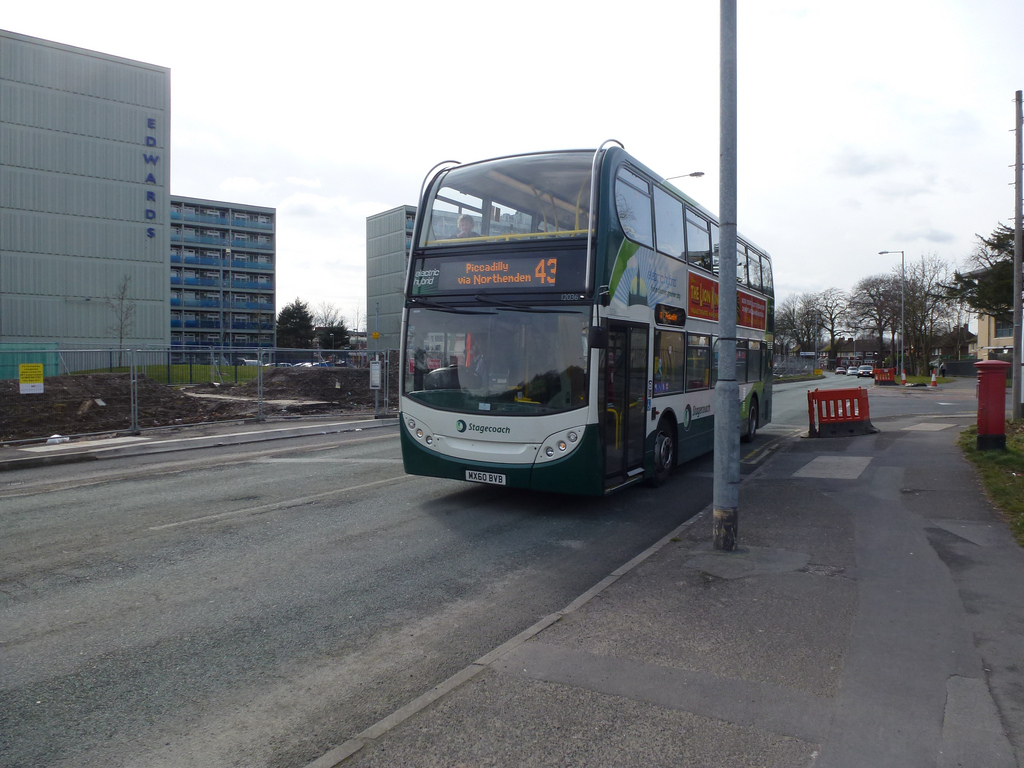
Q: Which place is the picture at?
A: It is at the sidewalk.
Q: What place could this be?
A: It is a sidewalk.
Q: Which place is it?
A: It is a sidewalk.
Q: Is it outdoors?
A: Yes, it is outdoors.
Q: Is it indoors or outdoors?
A: It is outdoors.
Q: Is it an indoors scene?
A: No, it is outdoors.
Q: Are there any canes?
A: No, there are no canes.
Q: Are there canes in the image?
A: No, there are no canes.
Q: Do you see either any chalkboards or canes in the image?
A: No, there are no canes or chalkboards.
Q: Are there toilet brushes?
A: No, there are no toilet brushes.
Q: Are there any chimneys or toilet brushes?
A: No, there are no toilet brushes or chimneys.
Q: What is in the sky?
A: The clouds are in the sky.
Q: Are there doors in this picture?
A: Yes, there is a door.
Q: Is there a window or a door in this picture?
A: Yes, there is a door.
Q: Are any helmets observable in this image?
A: No, there are no helmets.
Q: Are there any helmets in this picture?
A: No, there are no helmets.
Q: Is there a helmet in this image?
A: No, there are no helmets.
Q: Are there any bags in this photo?
A: No, there are no bags.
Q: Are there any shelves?
A: No, there are no shelves.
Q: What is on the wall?
A: The word is on the wall.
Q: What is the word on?
A: The word is on the wall.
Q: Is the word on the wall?
A: Yes, the word is on the wall.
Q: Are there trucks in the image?
A: No, there are no trucks.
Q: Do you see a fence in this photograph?
A: Yes, there is a fence.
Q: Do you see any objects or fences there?
A: Yes, there is a fence.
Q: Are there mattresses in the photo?
A: No, there are no mattresses.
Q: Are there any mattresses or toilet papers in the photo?
A: No, there are no mattresses or toilet papers.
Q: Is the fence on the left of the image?
A: Yes, the fence is on the left of the image.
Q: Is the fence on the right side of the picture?
A: No, the fence is on the left of the image.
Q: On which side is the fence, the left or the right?
A: The fence is on the left of the image.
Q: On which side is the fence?
A: The fence is on the left of the image.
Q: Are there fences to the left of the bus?
A: Yes, there is a fence to the left of the bus.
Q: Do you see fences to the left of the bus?
A: Yes, there is a fence to the left of the bus.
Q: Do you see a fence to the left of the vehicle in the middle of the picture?
A: Yes, there is a fence to the left of the bus.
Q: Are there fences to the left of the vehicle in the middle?
A: Yes, there is a fence to the left of the bus.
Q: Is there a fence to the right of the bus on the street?
A: No, the fence is to the left of the bus.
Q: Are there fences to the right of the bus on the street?
A: No, the fence is to the left of the bus.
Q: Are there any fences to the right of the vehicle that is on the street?
A: No, the fence is to the left of the bus.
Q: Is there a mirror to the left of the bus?
A: No, there is a fence to the left of the bus.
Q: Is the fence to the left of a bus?
A: Yes, the fence is to the left of a bus.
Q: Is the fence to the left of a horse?
A: No, the fence is to the left of a bus.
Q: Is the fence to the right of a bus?
A: No, the fence is to the left of a bus.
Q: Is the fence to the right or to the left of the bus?
A: The fence is to the left of the bus.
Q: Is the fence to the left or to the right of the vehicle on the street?
A: The fence is to the left of the bus.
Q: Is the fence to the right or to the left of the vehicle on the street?
A: The fence is to the left of the bus.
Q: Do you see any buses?
A: Yes, there is a bus.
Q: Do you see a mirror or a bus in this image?
A: Yes, there is a bus.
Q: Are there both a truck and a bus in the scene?
A: No, there is a bus but no trucks.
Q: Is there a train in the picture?
A: No, there are no trains.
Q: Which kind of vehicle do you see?
A: The vehicle is a bus.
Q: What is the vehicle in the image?
A: The vehicle is a bus.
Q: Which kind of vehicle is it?
A: The vehicle is a bus.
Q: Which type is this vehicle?
A: That is a bus.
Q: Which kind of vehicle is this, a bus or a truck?
A: That is a bus.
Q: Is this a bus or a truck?
A: This is a bus.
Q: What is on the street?
A: The bus is on the street.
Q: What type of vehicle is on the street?
A: The vehicle is a bus.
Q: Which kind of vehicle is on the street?
A: The vehicle is a bus.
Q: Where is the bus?
A: The bus is on the street.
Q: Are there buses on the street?
A: Yes, there is a bus on the street.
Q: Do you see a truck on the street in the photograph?
A: No, there is a bus on the street.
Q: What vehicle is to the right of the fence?
A: The vehicle is a bus.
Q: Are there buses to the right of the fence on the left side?
A: Yes, there is a bus to the right of the fence.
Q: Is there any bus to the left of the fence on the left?
A: No, the bus is to the right of the fence.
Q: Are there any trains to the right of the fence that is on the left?
A: No, there is a bus to the right of the fence.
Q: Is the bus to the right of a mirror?
A: No, the bus is to the right of the fence.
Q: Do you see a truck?
A: No, there are no trucks.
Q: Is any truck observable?
A: No, there are no trucks.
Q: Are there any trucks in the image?
A: No, there are no trucks.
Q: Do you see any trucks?
A: No, there are no trucks.